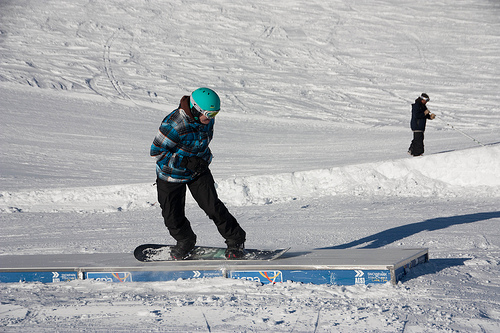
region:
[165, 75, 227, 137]
the helmet is green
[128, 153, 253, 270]
the pants are black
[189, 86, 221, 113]
light blue green helmet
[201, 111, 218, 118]
white snow goggles on face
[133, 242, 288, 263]
black snowboard on ramp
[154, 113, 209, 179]
blue plaid snow jacket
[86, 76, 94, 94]
tracks in powdery snow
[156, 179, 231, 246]
solid black snow pants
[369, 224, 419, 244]
dark shadow in snow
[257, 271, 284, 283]
yellow red and white illustration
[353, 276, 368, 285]
white letters on ramp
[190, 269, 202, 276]
white double arrows on ramp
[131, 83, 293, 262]
Person landing on snow ramp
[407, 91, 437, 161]
Person standing on the snow field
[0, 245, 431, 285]
Ramp on the snow field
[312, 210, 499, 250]
Shadow of the person on the snow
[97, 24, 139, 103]
Ski mark on the slope of the snow field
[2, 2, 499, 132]
sloped area on the snow field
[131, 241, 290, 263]
Black snowboard on the ramp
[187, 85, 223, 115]
Green helmet on the head of the person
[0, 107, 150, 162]
Untouched area in the snow field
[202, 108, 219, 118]
Goggles worn by the person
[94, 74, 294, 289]
the person is snowboarding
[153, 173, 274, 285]
person is wearing pants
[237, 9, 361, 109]
this is the ground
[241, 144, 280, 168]
the ground has snow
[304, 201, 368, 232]
this is the snow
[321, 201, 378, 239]
the snow is white inn color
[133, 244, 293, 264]
this is a snowboard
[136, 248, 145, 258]
the snowboard is black in color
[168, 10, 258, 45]
the snow has tracks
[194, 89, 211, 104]
this is a helmet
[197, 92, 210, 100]
the helmet is green in color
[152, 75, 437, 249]
these are two women